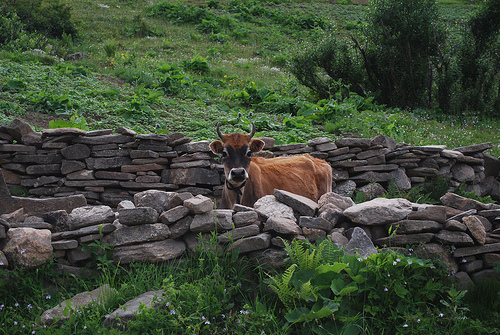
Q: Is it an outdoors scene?
A: Yes, it is outdoors.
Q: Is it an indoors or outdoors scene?
A: It is outdoors.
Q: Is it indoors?
A: No, it is outdoors.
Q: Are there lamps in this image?
A: No, there are no lamps.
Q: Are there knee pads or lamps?
A: No, there are no lamps or knee pads.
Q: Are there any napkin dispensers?
A: No, there are no napkin dispensers.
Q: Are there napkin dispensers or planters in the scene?
A: No, there are no napkin dispensers or planters.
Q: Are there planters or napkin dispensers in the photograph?
A: No, there are no napkin dispensers or planters.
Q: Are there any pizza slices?
A: No, there are no pizza slices.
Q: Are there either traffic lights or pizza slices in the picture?
A: No, there are no pizza slices or traffic lights.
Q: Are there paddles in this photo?
A: No, there are no paddles.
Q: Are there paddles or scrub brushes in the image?
A: No, there are no paddles or scrub brushes.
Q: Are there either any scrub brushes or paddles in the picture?
A: No, there are no paddles or scrub brushes.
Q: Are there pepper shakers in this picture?
A: No, there are no pepper shakers.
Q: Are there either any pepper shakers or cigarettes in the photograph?
A: No, there are no pepper shakers or cigarettes.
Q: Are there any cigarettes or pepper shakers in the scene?
A: No, there are no pepper shakers or cigarettes.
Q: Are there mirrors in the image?
A: No, there are no mirrors.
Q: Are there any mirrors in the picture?
A: No, there are no mirrors.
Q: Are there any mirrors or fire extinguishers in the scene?
A: No, there are no mirrors or fire extinguishers.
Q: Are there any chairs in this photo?
A: No, there are no chairs.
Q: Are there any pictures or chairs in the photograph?
A: No, there are no chairs or pictures.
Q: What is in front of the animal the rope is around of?
A: The wall is in front of the cow.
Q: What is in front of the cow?
A: The wall is in front of the cow.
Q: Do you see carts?
A: No, there are no carts.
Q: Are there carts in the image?
A: No, there are no carts.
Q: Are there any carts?
A: No, there are no carts.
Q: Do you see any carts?
A: No, there are no carts.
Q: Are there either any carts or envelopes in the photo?
A: No, there are no carts or envelopes.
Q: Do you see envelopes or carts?
A: No, there are no carts or envelopes.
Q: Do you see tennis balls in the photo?
A: No, there are no tennis balls.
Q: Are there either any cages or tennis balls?
A: No, there are no tennis balls or cages.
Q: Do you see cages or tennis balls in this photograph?
A: No, there are no tennis balls or cages.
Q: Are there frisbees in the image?
A: No, there are no frisbees.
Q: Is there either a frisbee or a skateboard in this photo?
A: No, there are no frisbees or skateboards.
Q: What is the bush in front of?
A: The bush is in front of the wall.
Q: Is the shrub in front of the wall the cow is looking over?
A: Yes, the shrub is in front of the wall.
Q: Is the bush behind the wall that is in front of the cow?
A: No, the bush is in front of the wall.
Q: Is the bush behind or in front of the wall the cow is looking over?
A: The bush is in front of the wall.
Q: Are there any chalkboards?
A: No, there are no chalkboards.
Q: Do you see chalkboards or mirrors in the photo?
A: No, there are no chalkboards or mirrors.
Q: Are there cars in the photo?
A: No, there are no cars.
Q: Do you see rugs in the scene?
A: No, there are no rugs.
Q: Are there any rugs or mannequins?
A: No, there are no rugs or mannequins.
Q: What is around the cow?
A: The rope is around the cow.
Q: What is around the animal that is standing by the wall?
A: The rope is around the cow.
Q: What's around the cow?
A: The rope is around the cow.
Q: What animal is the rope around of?
A: The rope is around the cow.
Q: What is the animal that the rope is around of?
A: The animal is a cow.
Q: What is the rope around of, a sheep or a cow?
A: The rope is around a cow.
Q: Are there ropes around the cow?
A: Yes, there is a rope around the cow.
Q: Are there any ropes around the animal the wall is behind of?
A: Yes, there is a rope around the cow.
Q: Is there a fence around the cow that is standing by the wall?
A: No, there is a rope around the cow.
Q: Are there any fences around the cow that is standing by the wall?
A: No, there is a rope around the cow.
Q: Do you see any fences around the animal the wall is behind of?
A: No, there is a rope around the cow.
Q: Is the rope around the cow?
A: Yes, the rope is around the cow.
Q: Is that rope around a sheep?
A: No, the rope is around the cow.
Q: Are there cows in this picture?
A: Yes, there is a cow.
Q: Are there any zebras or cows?
A: Yes, there is a cow.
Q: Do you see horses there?
A: No, there are no horses.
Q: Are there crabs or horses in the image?
A: No, there are no horses or crabs.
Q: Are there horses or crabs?
A: No, there are no horses or crabs.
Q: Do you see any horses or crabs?
A: No, there are no horses or crabs.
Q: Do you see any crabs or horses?
A: No, there are no horses or crabs.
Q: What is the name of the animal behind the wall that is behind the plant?
A: The animal is a cow.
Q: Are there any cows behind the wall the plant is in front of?
A: Yes, there is a cow behind the wall.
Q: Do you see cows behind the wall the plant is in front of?
A: Yes, there is a cow behind the wall.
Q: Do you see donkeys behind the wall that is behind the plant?
A: No, there is a cow behind the wall.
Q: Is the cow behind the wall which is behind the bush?
A: Yes, the cow is behind the wall.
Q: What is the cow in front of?
A: The cow is in front of the wall.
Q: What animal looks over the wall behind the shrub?
A: The cow looks over the wall.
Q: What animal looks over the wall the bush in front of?
A: The animal is a cow.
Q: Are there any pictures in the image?
A: No, there are no pictures.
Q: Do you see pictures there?
A: No, there are no pictures.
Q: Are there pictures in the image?
A: No, there are no pictures.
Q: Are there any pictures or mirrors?
A: No, there are no pictures or mirrors.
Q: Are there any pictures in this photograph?
A: No, there are no pictures.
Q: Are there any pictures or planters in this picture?
A: No, there are no pictures or planters.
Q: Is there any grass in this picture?
A: Yes, there is grass.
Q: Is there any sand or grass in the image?
A: Yes, there is grass.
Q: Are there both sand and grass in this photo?
A: No, there is grass but no sand.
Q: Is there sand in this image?
A: No, there is no sand.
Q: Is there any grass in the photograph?
A: Yes, there is grass.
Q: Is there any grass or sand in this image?
A: Yes, there is grass.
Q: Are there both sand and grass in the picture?
A: No, there is grass but no sand.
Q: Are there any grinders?
A: No, there are no grinders.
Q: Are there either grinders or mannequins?
A: No, there are no grinders or mannequins.